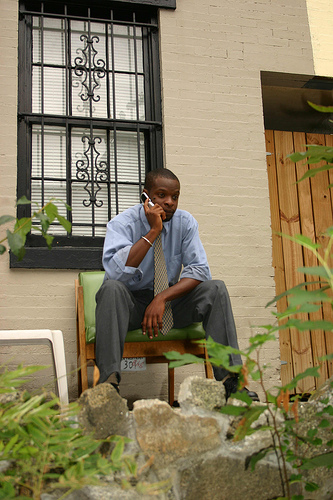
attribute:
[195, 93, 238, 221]
bricks — white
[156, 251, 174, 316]
tie — checked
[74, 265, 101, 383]
chair — green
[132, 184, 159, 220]
phone — cell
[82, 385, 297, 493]
formation — rock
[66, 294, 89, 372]
chair — wooden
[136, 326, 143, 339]
cushions — green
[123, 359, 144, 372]
sign — white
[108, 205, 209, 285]
shirt — blue, long sleeve 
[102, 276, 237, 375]
pants — grey , dress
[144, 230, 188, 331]
tie — dark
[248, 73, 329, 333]
door — wood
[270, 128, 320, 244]
boards — vertical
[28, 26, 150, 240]
grill — black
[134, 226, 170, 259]
bracelet — small silver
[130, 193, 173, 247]
hand — man's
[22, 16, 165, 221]
grate — black iron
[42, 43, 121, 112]
blinds — white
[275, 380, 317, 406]
bracket — black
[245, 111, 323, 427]
door — brown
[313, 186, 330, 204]
hole — tiny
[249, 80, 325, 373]
door — brown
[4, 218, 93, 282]
sill — black window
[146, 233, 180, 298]
tie — large multi colored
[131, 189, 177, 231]
neck — man's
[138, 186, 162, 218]
phone — cell, black and tan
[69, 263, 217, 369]
chair — large green and brown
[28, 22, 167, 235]
grate — black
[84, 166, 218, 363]
man — well dressed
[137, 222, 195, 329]
tie — yellow patterned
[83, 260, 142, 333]
cushion — green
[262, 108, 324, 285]
fence — wooden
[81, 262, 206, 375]
chair — wooden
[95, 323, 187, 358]
cushion — green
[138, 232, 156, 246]
bracelet — silver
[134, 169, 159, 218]
phone — silver and black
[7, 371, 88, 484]
plants — green leafy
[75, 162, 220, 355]
man — sitting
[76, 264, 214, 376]
chair — lime green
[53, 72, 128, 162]
bars — metal , black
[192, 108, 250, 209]
wall — rock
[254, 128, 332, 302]
door — wood